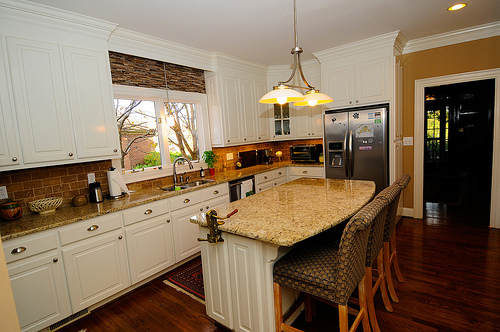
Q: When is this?
A: Daytime.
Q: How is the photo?
A: Clear.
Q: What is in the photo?
A: Dining set.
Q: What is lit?
A: Light.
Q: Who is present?
A: No one.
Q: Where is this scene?
A: In the kitchen.